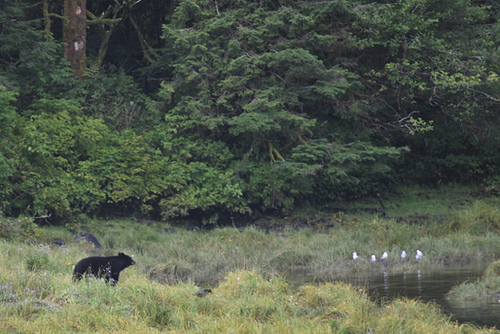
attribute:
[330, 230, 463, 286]
birds —  white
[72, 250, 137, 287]
bear —  Black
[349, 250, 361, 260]
bird —  a group,  white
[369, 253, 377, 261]
bird —  white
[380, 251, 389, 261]
bird —  white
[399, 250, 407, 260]
bird —  white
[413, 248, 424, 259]
bird —  white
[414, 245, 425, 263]
bird — in row,  white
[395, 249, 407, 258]
bird —  white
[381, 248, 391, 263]
bird —  white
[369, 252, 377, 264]
bird —  white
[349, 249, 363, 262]
bird —  white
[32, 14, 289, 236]
tree —  brown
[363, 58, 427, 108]
leaves —  green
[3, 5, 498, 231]
trees —  brown, brown 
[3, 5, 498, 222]
forest —  a scene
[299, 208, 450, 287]
birds —  white, a Flock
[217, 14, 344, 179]
trees —  brown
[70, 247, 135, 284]
bear —  black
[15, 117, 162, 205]
leaves —  green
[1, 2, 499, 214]
leaves —  green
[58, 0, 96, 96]
tree trunk — large, brown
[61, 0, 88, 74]
tree —  brown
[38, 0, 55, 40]
tree —  brown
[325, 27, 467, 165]
tree —  brown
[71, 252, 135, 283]
bear —  black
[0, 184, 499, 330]
grass —  tall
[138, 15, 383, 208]
trees —  heavy, of forest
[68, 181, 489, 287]
grass — wild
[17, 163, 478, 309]
grass — tall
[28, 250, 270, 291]
bird — grey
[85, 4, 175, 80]
trees — dead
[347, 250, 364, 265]
bird —  A flock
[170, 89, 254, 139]
leaves — green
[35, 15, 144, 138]
trees — brown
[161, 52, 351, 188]
leaves — green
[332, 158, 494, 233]
grass —  of forest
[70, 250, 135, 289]
bear —  black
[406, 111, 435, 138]
leaves —  green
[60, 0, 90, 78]
trees —  brown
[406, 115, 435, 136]
leaves —  green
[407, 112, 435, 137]
leaves —  leaves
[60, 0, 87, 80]
tree —  bare,  of forest